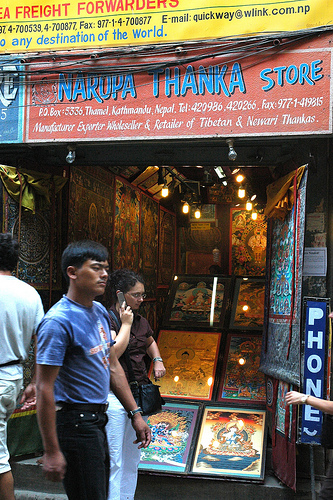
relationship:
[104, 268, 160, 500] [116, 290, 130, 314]
woman holding phone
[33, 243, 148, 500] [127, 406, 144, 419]
man wearing watch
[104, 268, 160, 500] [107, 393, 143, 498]
woman wearing pants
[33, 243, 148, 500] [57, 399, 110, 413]
man wearing belt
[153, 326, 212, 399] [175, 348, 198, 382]
painting of buddha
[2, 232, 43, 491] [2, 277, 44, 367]
man in shirt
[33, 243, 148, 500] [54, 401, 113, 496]
man with pants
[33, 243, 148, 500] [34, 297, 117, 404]
man wearing shirt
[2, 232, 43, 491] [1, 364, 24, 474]
man wearing shorts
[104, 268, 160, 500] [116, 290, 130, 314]
woman talking on phone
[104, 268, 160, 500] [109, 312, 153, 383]
woman wearing shirt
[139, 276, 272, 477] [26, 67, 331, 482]
art for store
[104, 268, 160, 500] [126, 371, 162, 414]
woman using bag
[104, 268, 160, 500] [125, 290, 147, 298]
woman wearing glasses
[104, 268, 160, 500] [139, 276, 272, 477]
woman looking at art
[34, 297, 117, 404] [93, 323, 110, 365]
shirt with image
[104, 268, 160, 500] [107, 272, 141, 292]
woman with hair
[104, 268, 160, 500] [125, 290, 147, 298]
woman with glasses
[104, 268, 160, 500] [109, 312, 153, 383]
woman with shirt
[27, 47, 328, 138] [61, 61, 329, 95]
sign with lettering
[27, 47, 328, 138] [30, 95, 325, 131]
sign with letters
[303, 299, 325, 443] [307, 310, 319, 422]
sign says phone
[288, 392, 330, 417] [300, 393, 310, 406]
forearm with watch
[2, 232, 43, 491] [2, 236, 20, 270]
man with hair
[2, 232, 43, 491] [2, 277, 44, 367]
man with shirt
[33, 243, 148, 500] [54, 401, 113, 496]
man wearing pants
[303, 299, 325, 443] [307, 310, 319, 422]
sign with phone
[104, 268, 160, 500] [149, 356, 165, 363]
woman wearing watch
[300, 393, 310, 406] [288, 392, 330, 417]
watch on top of arm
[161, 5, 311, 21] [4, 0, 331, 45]
email on front of sign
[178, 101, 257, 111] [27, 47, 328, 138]
number on front of sign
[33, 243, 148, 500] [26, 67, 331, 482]
man next to store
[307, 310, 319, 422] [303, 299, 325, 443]
phone on front of sign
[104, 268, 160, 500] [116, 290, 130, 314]
woman with phone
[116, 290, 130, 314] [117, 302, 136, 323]
phone in hand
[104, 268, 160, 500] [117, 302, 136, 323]
woman with hand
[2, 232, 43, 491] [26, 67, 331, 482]
man by store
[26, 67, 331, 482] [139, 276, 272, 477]
store full of art